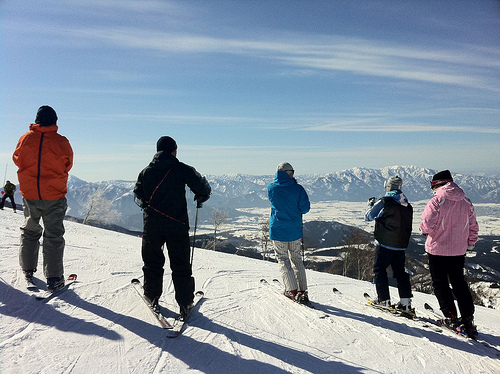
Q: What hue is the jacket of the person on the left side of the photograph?
A: Orange.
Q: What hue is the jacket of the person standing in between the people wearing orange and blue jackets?
A: Black.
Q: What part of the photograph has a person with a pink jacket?
A: On right.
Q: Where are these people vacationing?
A: A ski resort.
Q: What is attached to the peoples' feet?
A: Skis.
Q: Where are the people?
A: Ski slope.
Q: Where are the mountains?
A: Background.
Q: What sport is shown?
A: Skiing.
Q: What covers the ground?
A: Snow.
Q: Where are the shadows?
A: On ground.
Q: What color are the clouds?
A: White.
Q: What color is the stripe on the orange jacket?
A: Black.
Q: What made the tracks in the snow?
A: Skis.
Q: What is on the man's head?
A: Black hat.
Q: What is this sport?
A: Skiing.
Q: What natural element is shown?
A: Mountains.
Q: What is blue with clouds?
A: The sky.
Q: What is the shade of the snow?
A: White.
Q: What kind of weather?
A: Cold and snowy.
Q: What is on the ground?
A: White snow.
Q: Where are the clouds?
A: In the sky.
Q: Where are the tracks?
A: In the snow.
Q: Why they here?
A: To ski.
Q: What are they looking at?
A: The view.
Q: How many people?
A: 6.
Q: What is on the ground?
A: Snow.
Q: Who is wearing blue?
A: Person in the middle.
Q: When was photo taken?
A: During day.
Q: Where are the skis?
A: On their feet.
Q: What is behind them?
A: Shadows.